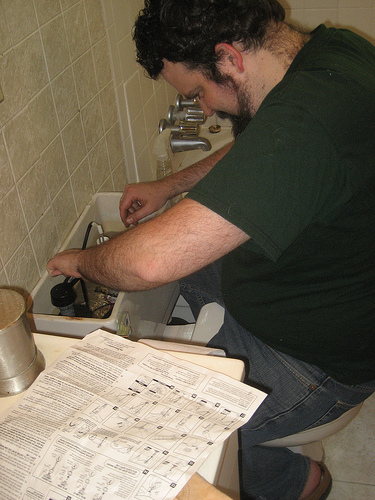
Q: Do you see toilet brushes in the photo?
A: No, there are no toilet brushes.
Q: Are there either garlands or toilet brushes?
A: No, there are no toilet brushes or garlands.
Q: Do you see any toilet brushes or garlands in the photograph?
A: No, there are no toilet brushes or garlands.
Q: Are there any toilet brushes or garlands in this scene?
A: No, there are no toilet brushes or garlands.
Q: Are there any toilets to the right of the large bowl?
A: Yes, there is a toilet to the right of the bowl.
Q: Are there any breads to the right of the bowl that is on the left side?
A: No, there is a toilet to the right of the bowl.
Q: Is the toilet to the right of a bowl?
A: Yes, the toilet is to the right of a bowl.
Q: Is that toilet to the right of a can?
A: No, the toilet is to the right of a bowl.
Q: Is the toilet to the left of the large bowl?
A: No, the toilet is to the right of the bowl.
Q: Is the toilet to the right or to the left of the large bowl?
A: The toilet is to the right of the bowl.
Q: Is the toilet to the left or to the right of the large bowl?
A: The toilet is to the right of the bowl.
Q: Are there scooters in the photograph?
A: No, there are no scooters.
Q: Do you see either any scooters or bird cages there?
A: No, there are no scooters or bird cages.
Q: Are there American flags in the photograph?
A: No, there are no American flags.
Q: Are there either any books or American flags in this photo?
A: No, there are no American flags or books.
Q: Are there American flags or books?
A: No, there are no American flags or books.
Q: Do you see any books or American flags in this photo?
A: No, there are no American flags or books.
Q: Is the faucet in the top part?
A: Yes, the faucet is in the top of the image.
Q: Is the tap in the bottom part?
A: No, the tap is in the top of the image.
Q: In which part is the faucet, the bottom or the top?
A: The faucet is in the top of the image.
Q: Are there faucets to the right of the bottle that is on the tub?
A: Yes, there is a faucet to the right of the bottle.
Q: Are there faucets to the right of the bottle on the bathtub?
A: Yes, there is a faucet to the right of the bottle.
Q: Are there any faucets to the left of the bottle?
A: No, the faucet is to the right of the bottle.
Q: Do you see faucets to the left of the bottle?
A: No, the faucet is to the right of the bottle.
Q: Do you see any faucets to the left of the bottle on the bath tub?
A: No, the faucet is to the right of the bottle.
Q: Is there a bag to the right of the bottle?
A: No, there is a faucet to the right of the bottle.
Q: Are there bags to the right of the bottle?
A: No, there is a faucet to the right of the bottle.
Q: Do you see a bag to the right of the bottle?
A: No, there is a faucet to the right of the bottle.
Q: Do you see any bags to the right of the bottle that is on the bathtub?
A: No, there is a faucet to the right of the bottle.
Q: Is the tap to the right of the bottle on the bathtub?
A: Yes, the tap is to the right of the bottle.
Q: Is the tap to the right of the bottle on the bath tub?
A: Yes, the tap is to the right of the bottle.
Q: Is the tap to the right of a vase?
A: No, the tap is to the right of the bottle.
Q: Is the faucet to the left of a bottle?
A: No, the faucet is to the right of a bottle.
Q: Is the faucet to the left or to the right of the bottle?
A: The faucet is to the right of the bottle.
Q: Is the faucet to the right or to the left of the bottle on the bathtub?
A: The faucet is to the right of the bottle.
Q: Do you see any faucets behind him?
A: Yes, there is a faucet behind the guy.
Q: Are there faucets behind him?
A: Yes, there is a faucet behind the guy.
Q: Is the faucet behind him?
A: Yes, the faucet is behind the guy.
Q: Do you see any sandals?
A: Yes, there are sandals.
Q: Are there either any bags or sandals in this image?
A: Yes, there are sandals.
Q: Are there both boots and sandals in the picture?
A: No, there are sandals but no boots.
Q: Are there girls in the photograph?
A: No, there are no girls.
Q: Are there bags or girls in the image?
A: No, there are no girls or bags.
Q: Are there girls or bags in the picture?
A: No, there are no girls or bags.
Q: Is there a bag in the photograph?
A: No, there are no bags.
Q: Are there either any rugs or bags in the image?
A: No, there are no bags or rugs.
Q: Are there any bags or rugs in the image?
A: No, there are no bags or rugs.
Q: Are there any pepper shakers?
A: No, there are no pepper shakers.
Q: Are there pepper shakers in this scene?
A: No, there are no pepper shakers.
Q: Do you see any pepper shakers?
A: No, there are no pepper shakers.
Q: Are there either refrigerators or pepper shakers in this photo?
A: No, there are no pepper shakers or refrigerators.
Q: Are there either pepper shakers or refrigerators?
A: No, there are no pepper shakers or refrigerators.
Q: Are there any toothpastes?
A: No, there are no toothpastes.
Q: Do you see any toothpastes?
A: No, there are no toothpastes.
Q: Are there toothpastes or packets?
A: No, there are no toothpastes or packets.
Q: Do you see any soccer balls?
A: No, there are no soccer balls.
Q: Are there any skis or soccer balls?
A: No, there are no soccer balls or skis.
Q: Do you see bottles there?
A: Yes, there is a bottle.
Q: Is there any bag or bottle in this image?
A: Yes, there is a bottle.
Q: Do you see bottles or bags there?
A: Yes, there is a bottle.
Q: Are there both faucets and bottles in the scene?
A: Yes, there are both a bottle and a faucet.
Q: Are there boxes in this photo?
A: No, there are no boxes.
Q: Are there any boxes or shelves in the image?
A: No, there are no boxes or shelves.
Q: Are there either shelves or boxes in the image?
A: No, there are no boxes or shelves.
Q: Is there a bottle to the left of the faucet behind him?
A: Yes, there is a bottle to the left of the tap.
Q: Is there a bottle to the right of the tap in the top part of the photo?
A: No, the bottle is to the left of the tap.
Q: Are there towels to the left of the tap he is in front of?
A: No, there is a bottle to the left of the tap.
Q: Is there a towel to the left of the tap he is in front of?
A: No, there is a bottle to the left of the tap.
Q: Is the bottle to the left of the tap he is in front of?
A: Yes, the bottle is to the left of the tap.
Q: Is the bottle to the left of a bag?
A: No, the bottle is to the left of the tap.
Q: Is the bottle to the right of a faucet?
A: No, the bottle is to the left of a faucet.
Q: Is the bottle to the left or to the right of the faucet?
A: The bottle is to the left of the faucet.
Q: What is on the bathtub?
A: The bottle is on the bathtub.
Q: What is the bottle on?
A: The bottle is on the tub.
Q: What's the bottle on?
A: The bottle is on the tub.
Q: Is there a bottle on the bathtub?
A: Yes, there is a bottle on the bathtub.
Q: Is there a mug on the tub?
A: No, there is a bottle on the tub.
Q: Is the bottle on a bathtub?
A: Yes, the bottle is on a bathtub.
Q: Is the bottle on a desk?
A: No, the bottle is on a bathtub.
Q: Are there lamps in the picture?
A: No, there are no lamps.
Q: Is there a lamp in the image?
A: No, there are no lamps.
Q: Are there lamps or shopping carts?
A: No, there are no lamps or shopping carts.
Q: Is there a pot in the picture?
A: No, there are no pots.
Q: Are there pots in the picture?
A: No, there are no pots.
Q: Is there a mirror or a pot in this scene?
A: No, there are no pots or mirrors.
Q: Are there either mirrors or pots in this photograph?
A: No, there are no pots or mirrors.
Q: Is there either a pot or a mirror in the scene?
A: No, there are no pots or mirrors.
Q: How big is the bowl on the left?
A: The bowl is large.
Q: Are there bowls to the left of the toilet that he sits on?
A: Yes, there is a bowl to the left of the toilet.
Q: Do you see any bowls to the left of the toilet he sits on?
A: Yes, there is a bowl to the left of the toilet.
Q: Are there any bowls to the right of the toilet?
A: No, the bowl is to the left of the toilet.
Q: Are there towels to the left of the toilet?
A: No, there is a bowl to the left of the toilet.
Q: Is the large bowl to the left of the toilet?
A: Yes, the bowl is to the left of the toilet.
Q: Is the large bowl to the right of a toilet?
A: No, the bowl is to the left of a toilet.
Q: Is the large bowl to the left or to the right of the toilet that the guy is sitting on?
A: The bowl is to the left of the toilet.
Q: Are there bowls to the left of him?
A: Yes, there is a bowl to the left of the guy.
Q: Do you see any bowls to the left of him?
A: Yes, there is a bowl to the left of the guy.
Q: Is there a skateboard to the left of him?
A: No, there is a bowl to the left of the guy.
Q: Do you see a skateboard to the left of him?
A: No, there is a bowl to the left of the guy.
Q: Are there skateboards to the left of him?
A: No, there is a bowl to the left of the guy.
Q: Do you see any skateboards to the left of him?
A: No, there is a bowl to the left of the guy.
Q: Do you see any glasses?
A: No, there are no glasses.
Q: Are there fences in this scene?
A: No, there are no fences.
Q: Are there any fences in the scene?
A: No, there are no fences.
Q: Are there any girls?
A: No, there are no girls.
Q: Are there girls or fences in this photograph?
A: No, there are no girls or fences.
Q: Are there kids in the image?
A: No, there are no kids.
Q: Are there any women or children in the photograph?
A: No, there are no children or women.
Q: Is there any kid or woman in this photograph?
A: No, there are no children or women.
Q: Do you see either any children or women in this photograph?
A: No, there are no children or women.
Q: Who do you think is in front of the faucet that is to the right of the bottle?
A: The guy is in front of the tap.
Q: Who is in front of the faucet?
A: The guy is in front of the tap.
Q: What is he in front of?
A: The guy is in front of the tap.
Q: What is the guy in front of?
A: The guy is in front of the tap.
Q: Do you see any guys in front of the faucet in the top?
A: Yes, there is a guy in front of the tap.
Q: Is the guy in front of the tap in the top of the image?
A: Yes, the guy is in front of the tap.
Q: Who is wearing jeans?
A: The guy is wearing jeans.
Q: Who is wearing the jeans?
A: The guy is wearing jeans.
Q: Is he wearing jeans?
A: Yes, the guy is wearing jeans.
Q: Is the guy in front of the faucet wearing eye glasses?
A: No, the guy is wearing jeans.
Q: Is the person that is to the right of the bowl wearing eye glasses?
A: No, the guy is wearing jeans.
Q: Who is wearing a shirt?
A: The guy is wearing a shirt.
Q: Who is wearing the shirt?
A: The guy is wearing a shirt.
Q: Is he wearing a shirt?
A: Yes, the guy is wearing a shirt.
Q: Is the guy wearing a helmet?
A: No, the guy is wearing a shirt.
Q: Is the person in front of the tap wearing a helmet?
A: No, the guy is wearing a shirt.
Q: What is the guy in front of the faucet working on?
A: The guy is working on the bowl.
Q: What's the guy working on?
A: The guy is working on the bowl.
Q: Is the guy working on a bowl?
A: Yes, the guy is working on a bowl.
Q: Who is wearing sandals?
A: The guy is wearing sandals.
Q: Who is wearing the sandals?
A: The guy is wearing sandals.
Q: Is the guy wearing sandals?
A: Yes, the guy is wearing sandals.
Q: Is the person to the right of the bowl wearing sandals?
A: Yes, the guy is wearing sandals.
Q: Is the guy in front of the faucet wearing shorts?
A: No, the guy is wearing sandals.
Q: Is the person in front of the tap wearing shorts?
A: No, the guy is wearing sandals.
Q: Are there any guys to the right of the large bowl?
A: Yes, there is a guy to the right of the bowl.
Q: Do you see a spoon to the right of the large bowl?
A: No, there is a guy to the right of the bowl.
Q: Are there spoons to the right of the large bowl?
A: No, there is a guy to the right of the bowl.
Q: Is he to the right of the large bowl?
A: Yes, the guy is to the right of the bowl.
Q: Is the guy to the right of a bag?
A: No, the guy is to the right of the bowl.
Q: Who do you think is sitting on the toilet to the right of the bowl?
A: The guy is sitting on the toilet.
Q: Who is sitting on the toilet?
A: The guy is sitting on the toilet.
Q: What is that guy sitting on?
A: The guy is sitting on the toilet.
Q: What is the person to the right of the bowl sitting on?
A: The guy is sitting on the toilet.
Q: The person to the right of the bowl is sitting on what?
A: The guy is sitting on the toilet.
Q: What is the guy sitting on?
A: The guy is sitting on the toilet.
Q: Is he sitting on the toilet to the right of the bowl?
A: Yes, the guy is sitting on the toilet.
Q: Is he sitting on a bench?
A: No, the guy is sitting on the toilet.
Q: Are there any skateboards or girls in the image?
A: No, there are no girls or skateboards.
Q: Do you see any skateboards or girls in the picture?
A: No, there are no girls or skateboards.